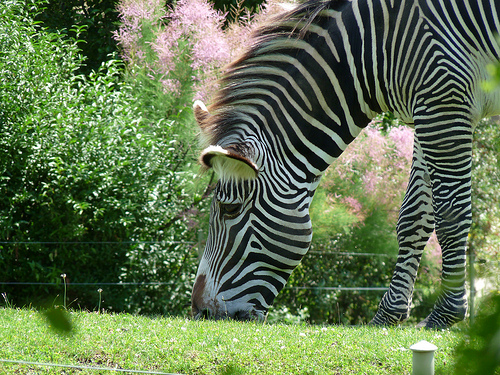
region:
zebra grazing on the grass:
[188, 0, 498, 332]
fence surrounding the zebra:
[0, 242, 496, 373]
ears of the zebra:
[187, 95, 274, 182]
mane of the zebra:
[193, 0, 325, 145]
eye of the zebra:
[210, 192, 245, 223]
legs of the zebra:
[366, 86, 479, 328]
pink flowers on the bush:
[106, 0, 473, 268]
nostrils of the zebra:
[195, 304, 214, 322]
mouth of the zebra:
[226, 307, 255, 326]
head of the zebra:
[189, 144, 318, 329]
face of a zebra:
[181, 99, 318, 319]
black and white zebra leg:
[401, 47, 485, 328]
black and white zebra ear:
[189, 126, 271, 183]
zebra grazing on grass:
[191, 82, 315, 359]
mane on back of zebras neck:
[209, 5, 326, 121]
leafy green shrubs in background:
[17, 47, 154, 269]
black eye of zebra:
[219, 195, 245, 221]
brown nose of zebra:
[189, 271, 210, 316]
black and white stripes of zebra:
[281, 36, 373, 126]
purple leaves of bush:
[111, 1, 218, 70]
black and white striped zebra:
[195, 7, 496, 314]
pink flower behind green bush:
[102, 2, 242, 99]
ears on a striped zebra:
[182, 99, 265, 189]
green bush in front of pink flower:
[5, 22, 211, 299]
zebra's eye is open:
[217, 185, 247, 220]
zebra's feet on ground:
[361, 287, 473, 329]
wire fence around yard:
[4, 220, 497, 373]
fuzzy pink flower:
[119, 2, 224, 82]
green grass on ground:
[18, 304, 450, 371]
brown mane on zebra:
[206, 51, 261, 143]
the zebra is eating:
[187, 85, 287, 327]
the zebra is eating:
[142, 65, 324, 355]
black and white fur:
[151, 23, 471, 357]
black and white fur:
[184, 90, 340, 294]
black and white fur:
[300, 43, 447, 160]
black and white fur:
[398, 80, 475, 368]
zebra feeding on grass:
[170, 23, 337, 335]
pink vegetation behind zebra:
[126, 2, 233, 90]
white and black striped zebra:
[183, 5, 485, 313]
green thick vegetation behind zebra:
[0, 11, 180, 328]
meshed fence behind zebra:
[12, 225, 389, 322]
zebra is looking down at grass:
[174, 16, 476, 328]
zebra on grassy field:
[5, 195, 480, 365]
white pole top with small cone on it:
[400, 333, 440, 371]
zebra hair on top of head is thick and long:
[171, 9, 357, 157]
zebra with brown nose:
[166, 94, 325, 329]